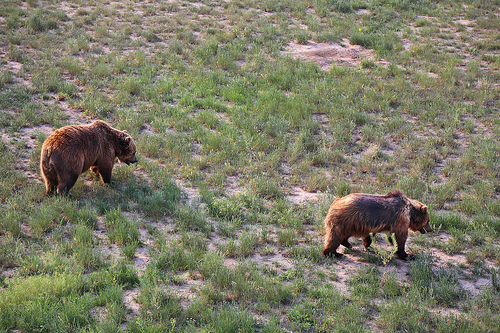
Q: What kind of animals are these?
A: Bears.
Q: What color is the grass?
A: Green.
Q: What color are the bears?
A: Brown.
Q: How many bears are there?
A: Two.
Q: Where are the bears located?
A: On the grass.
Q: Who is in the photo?
A: There are no people.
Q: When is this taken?
A: During the day.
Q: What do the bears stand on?
A: Ground.